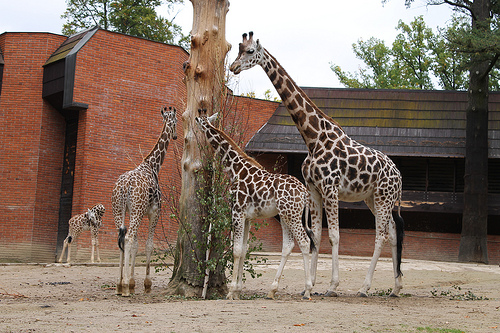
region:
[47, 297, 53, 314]
black mark is spotted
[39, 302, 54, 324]
black mark is spotted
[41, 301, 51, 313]
black mark is spotted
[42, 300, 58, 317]
black mark is spotted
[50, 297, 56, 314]
black mark is spotted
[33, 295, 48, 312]
black mark is spotted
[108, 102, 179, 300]
A giraffe facing two other giraffes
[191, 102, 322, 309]
A young giraffe standing with a larger giraffe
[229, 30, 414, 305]
A large giraffe standing with a younger giraffe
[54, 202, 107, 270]
A giraffe in the background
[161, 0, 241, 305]
A tree with branches and limbs cut off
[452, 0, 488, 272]
Another tree with its lower branches and limbs cut off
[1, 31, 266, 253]
A large brick building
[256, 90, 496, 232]
A wooden building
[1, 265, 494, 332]
dirt-lot of the giraffe's area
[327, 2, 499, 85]
Leafy tree outside of the pen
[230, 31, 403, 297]
an adult giraffe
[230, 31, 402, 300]
the largest giraffe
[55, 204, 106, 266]
the smallest giraffe of the group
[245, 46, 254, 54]
a giraffe's left eye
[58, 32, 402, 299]
a family of giraffes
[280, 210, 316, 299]
a giraffe's left rear leg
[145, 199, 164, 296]
a giraffe's right front leg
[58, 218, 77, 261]
a baby giraffe's rear legs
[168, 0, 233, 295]
a tree stripped of bark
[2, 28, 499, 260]
a brick building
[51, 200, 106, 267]
smallest giraffe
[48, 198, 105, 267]
little giraffe with his neck bent to the left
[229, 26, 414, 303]
tallest giraffe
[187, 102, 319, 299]
medium giraffe standing next to the tall giraffe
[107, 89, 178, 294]
medium giraffe standing between the other medium giraffe and the baby giraffe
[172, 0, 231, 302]
tree in which the medium and large giraffe are eating from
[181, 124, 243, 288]
green leafy vegetation the giraffes are eating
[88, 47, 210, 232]
brick building in which the baby giraffe is standing next to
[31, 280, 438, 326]
dirt ground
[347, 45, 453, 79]
green leafy tree branches behind the building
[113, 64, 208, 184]
the wall is red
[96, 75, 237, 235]
the wall is red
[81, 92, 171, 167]
the wall is red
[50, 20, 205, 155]
the wall is red